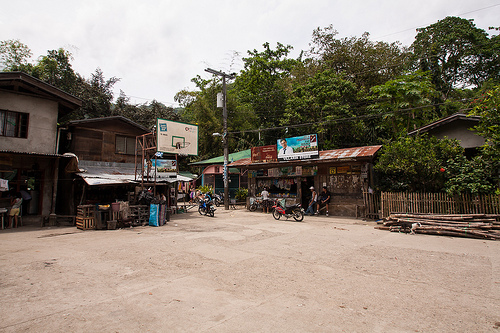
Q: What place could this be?
A: It is a field.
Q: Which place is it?
A: It is a field.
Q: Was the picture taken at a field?
A: Yes, it was taken in a field.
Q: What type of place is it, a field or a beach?
A: It is a field.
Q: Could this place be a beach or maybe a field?
A: It is a field.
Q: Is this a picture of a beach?
A: No, the picture is showing a field.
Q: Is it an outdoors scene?
A: Yes, it is outdoors.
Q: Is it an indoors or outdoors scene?
A: It is outdoors.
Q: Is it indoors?
A: No, it is outdoors.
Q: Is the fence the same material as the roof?
A: No, the fence is made of wood and the roof is made of metal.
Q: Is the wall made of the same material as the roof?
A: No, the wall is made of cement and the roof is made of metal.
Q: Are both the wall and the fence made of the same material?
A: No, the wall is made of concrete and the fence is made of wood.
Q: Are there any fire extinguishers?
A: No, there are no fire extinguishers.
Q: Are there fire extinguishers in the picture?
A: No, there are no fire extinguishers.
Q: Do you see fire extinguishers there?
A: No, there are no fire extinguishers.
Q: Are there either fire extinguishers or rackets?
A: No, there are no fire extinguishers or rackets.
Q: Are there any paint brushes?
A: No, there are no paint brushes.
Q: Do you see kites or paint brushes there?
A: No, there are no paint brushes or kites.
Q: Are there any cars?
A: No, there are no cars.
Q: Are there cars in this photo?
A: No, there are no cars.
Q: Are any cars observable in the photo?
A: No, there are no cars.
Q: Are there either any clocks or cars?
A: No, there are no cars or clocks.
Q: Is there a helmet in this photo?
A: No, there are no helmets.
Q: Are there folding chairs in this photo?
A: No, there are no folding chairs.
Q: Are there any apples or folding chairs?
A: No, there are no folding chairs or apples.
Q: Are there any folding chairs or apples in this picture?
A: No, there are no folding chairs or apples.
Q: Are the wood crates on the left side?
A: Yes, the crates are on the left of the image.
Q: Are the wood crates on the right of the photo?
A: No, the crates are on the left of the image.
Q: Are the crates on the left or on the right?
A: The crates are on the left of the image.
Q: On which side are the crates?
A: The crates are on the left of the image.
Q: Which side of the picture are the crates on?
A: The crates are on the left of the image.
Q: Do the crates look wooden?
A: Yes, the crates are wooden.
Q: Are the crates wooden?
A: Yes, the crates are wooden.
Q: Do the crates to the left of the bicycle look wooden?
A: Yes, the crates are wooden.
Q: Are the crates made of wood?
A: Yes, the crates are made of wood.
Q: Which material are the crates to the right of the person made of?
A: The crates are made of wood.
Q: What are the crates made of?
A: The crates are made of wood.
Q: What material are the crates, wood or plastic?
A: The crates are made of wood.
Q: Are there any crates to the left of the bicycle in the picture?
A: Yes, there are crates to the left of the bicycle.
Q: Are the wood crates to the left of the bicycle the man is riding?
A: Yes, the crates are to the left of the bicycle.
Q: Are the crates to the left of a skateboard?
A: No, the crates are to the left of the bicycle.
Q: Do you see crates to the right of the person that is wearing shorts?
A: Yes, there are crates to the right of the person.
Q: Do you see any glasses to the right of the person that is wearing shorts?
A: No, there are crates to the right of the person.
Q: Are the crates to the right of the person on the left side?
A: Yes, the crates are to the right of the person.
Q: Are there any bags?
A: No, there are no bags.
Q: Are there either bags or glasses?
A: No, there are no bags or glasses.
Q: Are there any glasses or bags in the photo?
A: No, there are no bags or glasses.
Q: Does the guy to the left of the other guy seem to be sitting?
A: Yes, the guy is sitting.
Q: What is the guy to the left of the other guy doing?
A: The guy is sitting.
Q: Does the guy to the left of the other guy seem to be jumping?
A: No, the guy is sitting.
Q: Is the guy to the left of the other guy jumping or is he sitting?
A: The guy is sitting.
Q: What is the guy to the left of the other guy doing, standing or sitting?
A: The guy is sitting.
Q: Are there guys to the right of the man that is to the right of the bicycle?
A: Yes, there is a guy to the right of the man.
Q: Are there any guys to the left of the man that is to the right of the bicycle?
A: No, the guy is to the right of the man.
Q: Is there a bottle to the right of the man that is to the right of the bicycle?
A: No, there is a guy to the right of the man.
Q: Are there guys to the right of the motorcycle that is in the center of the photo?
A: Yes, there is a guy to the right of the motorcycle.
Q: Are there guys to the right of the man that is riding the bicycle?
A: Yes, there is a guy to the right of the man.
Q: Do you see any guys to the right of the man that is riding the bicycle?
A: Yes, there is a guy to the right of the man.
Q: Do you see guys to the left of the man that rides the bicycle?
A: No, the guy is to the right of the man.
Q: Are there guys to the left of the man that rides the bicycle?
A: No, the guy is to the right of the man.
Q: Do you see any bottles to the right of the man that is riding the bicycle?
A: No, there is a guy to the right of the man.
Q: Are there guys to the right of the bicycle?
A: Yes, there is a guy to the right of the bicycle.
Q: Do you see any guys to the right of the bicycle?
A: Yes, there is a guy to the right of the bicycle.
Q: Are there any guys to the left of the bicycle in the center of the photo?
A: No, the guy is to the right of the bicycle.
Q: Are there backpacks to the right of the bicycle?
A: No, there is a guy to the right of the bicycle.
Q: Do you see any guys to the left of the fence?
A: Yes, there is a guy to the left of the fence.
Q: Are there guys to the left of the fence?
A: Yes, there is a guy to the left of the fence.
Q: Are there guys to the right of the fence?
A: No, the guy is to the left of the fence.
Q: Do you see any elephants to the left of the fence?
A: No, there is a guy to the left of the fence.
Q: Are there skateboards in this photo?
A: No, there are no skateboards.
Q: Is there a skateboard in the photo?
A: No, there are no skateboards.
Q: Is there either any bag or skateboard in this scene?
A: No, there are no skateboards or bags.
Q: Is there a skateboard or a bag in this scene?
A: No, there are no skateboards or bags.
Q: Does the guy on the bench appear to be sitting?
A: Yes, the guy is sitting.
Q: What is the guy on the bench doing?
A: The guy is sitting.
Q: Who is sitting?
A: The guy is sitting.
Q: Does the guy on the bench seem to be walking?
A: No, the guy is sitting.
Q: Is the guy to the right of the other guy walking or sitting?
A: The guy is sitting.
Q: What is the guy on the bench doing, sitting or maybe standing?
A: The guy is sitting.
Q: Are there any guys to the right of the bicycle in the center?
A: Yes, there is a guy to the right of the bicycle.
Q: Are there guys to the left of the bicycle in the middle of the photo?
A: No, the guy is to the right of the bicycle.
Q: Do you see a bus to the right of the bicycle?
A: No, there is a guy to the right of the bicycle.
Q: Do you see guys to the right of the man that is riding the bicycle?
A: Yes, there is a guy to the right of the man.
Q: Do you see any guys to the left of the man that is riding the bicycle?
A: No, the guy is to the right of the man.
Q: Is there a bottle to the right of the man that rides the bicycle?
A: No, there is a guy to the right of the man.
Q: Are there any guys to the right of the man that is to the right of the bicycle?
A: Yes, there is a guy to the right of the man.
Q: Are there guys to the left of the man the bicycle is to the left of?
A: No, the guy is to the right of the man.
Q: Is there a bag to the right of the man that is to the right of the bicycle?
A: No, there is a guy to the right of the man.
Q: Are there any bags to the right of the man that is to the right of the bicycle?
A: No, there is a guy to the right of the man.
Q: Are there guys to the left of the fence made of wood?
A: Yes, there is a guy to the left of the fence.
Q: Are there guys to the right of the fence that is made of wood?
A: No, the guy is to the left of the fence.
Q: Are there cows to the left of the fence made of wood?
A: No, there is a guy to the left of the fence.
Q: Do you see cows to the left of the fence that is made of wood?
A: No, there is a guy to the left of the fence.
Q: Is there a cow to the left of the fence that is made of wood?
A: No, there is a guy to the left of the fence.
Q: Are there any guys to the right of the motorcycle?
A: Yes, there is a guy to the right of the motorcycle.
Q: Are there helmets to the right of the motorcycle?
A: No, there is a guy to the right of the motorcycle.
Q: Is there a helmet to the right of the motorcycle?
A: No, there is a guy to the right of the motorcycle.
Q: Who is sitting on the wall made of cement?
A: The guy is sitting on the wall.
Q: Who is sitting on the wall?
A: The guy is sitting on the wall.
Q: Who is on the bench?
A: The guy is on the bench.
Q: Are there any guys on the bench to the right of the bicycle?
A: Yes, there is a guy on the bench.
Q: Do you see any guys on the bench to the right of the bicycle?
A: Yes, there is a guy on the bench.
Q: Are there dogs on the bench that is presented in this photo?
A: No, there is a guy on the bench.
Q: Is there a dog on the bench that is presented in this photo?
A: No, there is a guy on the bench.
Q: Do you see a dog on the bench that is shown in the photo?
A: No, there is a guy on the bench.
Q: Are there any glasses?
A: No, there are no glasses.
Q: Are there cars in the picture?
A: No, there are no cars.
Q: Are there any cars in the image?
A: No, there are no cars.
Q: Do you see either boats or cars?
A: No, there are no cars or boats.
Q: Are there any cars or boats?
A: No, there are no cars or boats.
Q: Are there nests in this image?
A: No, there are no nests.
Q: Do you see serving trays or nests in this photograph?
A: No, there are no nests or serving trays.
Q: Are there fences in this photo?
A: Yes, there is a fence.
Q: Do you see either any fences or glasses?
A: Yes, there is a fence.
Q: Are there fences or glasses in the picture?
A: Yes, there is a fence.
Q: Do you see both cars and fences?
A: No, there is a fence but no cars.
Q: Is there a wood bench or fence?
A: Yes, there is a wood fence.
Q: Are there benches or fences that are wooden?
A: Yes, the fence is wooden.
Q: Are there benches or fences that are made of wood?
A: Yes, the fence is made of wood.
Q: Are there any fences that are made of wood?
A: Yes, there is a fence that is made of wood.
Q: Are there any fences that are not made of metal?
A: Yes, there is a fence that is made of wood.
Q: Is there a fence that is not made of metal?
A: Yes, there is a fence that is made of wood.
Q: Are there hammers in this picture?
A: No, there are no hammers.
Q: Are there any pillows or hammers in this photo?
A: No, there are no hammers or pillows.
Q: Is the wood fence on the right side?
A: Yes, the fence is on the right of the image.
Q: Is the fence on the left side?
A: No, the fence is on the right of the image.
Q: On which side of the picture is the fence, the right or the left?
A: The fence is on the right of the image.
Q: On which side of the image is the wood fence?
A: The fence is on the right of the image.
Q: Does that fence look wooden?
A: Yes, the fence is wooden.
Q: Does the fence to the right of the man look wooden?
A: Yes, the fence is wooden.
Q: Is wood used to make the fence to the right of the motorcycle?
A: Yes, the fence is made of wood.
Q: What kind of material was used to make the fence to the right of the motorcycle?
A: The fence is made of wood.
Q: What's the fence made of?
A: The fence is made of wood.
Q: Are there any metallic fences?
A: No, there is a fence but it is wooden.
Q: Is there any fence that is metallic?
A: No, there is a fence but it is wooden.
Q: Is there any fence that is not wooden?
A: No, there is a fence but it is wooden.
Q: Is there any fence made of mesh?
A: No, there is a fence but it is made of wood.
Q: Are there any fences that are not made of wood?
A: No, there is a fence but it is made of wood.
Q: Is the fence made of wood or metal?
A: The fence is made of wood.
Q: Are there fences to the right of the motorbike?
A: Yes, there is a fence to the right of the motorbike.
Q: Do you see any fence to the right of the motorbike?
A: Yes, there is a fence to the right of the motorbike.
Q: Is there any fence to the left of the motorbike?
A: No, the fence is to the right of the motorbike.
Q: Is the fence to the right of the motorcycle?
A: Yes, the fence is to the right of the motorcycle.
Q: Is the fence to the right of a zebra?
A: No, the fence is to the right of the motorcycle.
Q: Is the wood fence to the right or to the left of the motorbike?
A: The fence is to the right of the motorbike.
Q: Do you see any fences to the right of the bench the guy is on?
A: Yes, there is a fence to the right of the bench.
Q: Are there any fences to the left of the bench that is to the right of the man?
A: No, the fence is to the right of the bench.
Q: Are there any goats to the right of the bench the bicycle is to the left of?
A: No, there is a fence to the right of the bench.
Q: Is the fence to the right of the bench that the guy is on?
A: Yes, the fence is to the right of the bench.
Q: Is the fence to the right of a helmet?
A: No, the fence is to the right of the bench.